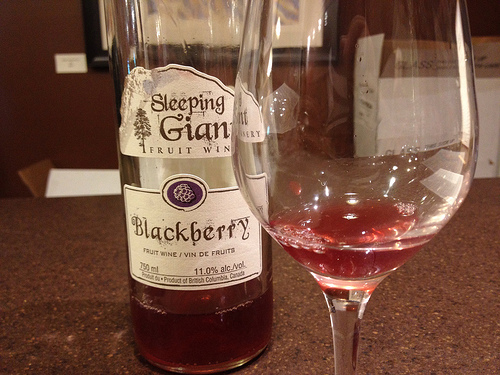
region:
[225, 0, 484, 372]
a wine glass is on the table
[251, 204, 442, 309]
a red wine is in the glass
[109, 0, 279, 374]
a bottle of wine is next to the glass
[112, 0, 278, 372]
the wine bottle is on the table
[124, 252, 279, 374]
a wine bottle is almost empty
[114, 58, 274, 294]
a label is on the wine bottle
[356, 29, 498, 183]
an opened box is behind the table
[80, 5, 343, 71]
a framed picture is on the wall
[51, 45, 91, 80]
an information card is next to the art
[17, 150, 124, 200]
an opened box is on the floor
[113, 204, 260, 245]
flavor of the wine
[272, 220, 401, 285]
small amount of wine at the bottom of the glass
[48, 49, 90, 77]
white tag on the wall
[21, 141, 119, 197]
flaps of a cardboard box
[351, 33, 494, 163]
white cardboard box behind the glass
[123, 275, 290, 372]
bottle of wine is almost empty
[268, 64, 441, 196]
reflections in the wine glass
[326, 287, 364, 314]
reflection through the stem of the glass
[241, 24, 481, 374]
wine glass on the counter top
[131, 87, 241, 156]
the wine logo and name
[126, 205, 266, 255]
the flavor of the wine is blackberry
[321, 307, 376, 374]
the handle of the wine glass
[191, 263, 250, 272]
the alcohol percentage of the wine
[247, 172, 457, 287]
some wine in the glass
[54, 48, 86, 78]
a light switch on the wall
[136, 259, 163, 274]
the number of ML in the bottle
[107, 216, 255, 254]
black writing on bottle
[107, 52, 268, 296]
white label on front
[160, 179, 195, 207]
purple logo on middle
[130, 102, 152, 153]
brown tree on label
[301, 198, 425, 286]
red liquid in the glass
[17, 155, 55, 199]
cardboard box in back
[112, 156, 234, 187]
silver on the label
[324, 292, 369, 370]
stem piece of glass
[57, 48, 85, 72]
white outlet on the wall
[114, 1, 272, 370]
A mostly empty bottle of fruit wine.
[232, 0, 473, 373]
Wine glass still holding a little liquid.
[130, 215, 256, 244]
The word 'Blackberry' in a curly font on a label.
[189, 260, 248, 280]
Declaration of the percentage of alcohol by volume on a bottle.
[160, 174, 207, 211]
Logo image depicting a purple bunch of grapes.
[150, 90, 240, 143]
Producer's company name on a label.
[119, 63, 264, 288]
Whit and silver label on a bottle.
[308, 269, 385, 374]
The stem on a wine glass.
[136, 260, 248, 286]
Legally required information on a bottle of alcohol.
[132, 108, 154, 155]
Small graphic of an evergreen tree.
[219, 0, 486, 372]
a glass of wine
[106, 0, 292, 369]
a bottle of wine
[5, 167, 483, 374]
a marble counter top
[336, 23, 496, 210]
a white box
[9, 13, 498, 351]
a scene inside